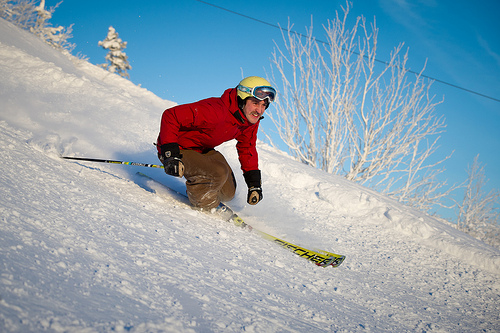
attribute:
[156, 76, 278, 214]
man — skiing, crouched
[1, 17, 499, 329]
snow — white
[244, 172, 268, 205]
glove — black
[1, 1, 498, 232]
sky — cloudless, blue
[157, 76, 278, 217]
person — skiing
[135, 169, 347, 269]
skis — yellow, black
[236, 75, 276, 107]
helmet — yellow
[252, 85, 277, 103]
goggles — blue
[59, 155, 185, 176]
pole — black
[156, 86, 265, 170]
coat — red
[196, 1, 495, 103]
cord — black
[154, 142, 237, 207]
pants — brown, tan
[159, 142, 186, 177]
gloves — black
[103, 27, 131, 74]
tree — snow-covered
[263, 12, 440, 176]
tree — leafless, bare